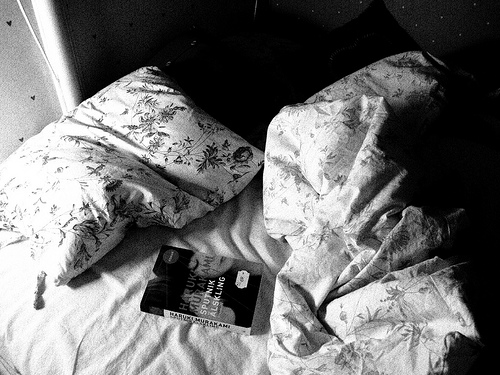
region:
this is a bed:
[3, 44, 485, 372]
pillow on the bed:
[3, 41, 272, 286]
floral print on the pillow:
[8, 67, 285, 277]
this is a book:
[106, 215, 285, 350]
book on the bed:
[17, 68, 444, 372]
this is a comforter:
[218, 48, 494, 373]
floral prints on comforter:
[245, 22, 492, 373]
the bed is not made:
[16, 53, 461, 373]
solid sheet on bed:
[23, 193, 328, 372]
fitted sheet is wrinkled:
[5, 162, 307, 373]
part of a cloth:
[394, 238, 409, 256]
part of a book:
[233, 269, 238, 281]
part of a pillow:
[65, 237, 76, 253]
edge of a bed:
[135, 315, 139, 325]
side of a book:
[237, 298, 243, 306]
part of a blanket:
[336, 251, 352, 272]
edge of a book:
[213, 290, 218, 295]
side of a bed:
[112, 286, 122, 308]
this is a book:
[127, 235, 272, 340]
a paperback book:
[115, 240, 270, 335]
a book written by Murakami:
[135, 240, 266, 340]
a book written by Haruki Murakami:
[135, 235, 256, 337]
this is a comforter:
[270, 50, 495, 372]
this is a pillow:
[1, 55, 261, 281]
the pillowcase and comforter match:
[0, 46, 472, 371]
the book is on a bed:
[120, 235, 277, 340]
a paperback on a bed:
[133, 242, 268, 337]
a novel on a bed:
[122, 234, 274, 339]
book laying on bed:
[136, 237, 278, 340]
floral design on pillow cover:
[163, 140, 240, 172]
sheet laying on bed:
[278, 69, 466, 374]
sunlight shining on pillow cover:
[0, 114, 90, 293]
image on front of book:
[145, 248, 258, 319]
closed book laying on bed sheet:
[121, 242, 272, 342]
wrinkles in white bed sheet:
[93, 280, 138, 358]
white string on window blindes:
[1, 0, 63, 95]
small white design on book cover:
[226, 263, 257, 293]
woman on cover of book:
[164, 240, 236, 297]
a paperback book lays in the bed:
[142, 246, 263, 341]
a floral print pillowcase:
[0, 62, 261, 279]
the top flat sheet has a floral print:
[263, 47, 473, 358]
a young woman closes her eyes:
[145, 236, 260, 288]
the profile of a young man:
[138, 274, 240, 334]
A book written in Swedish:
[198, 261, 227, 330]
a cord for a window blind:
[11, 0, 74, 106]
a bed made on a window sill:
[41, 1, 498, 294]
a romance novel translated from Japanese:
[141, 241, 267, 331]